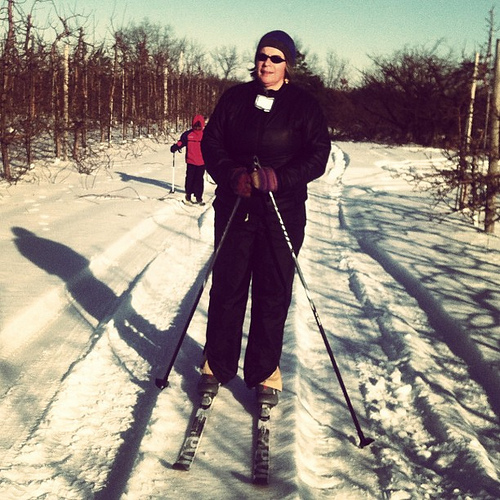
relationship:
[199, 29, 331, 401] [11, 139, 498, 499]
person on trail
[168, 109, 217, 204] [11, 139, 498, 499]
skier on trail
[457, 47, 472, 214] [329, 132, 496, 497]
tree of trail side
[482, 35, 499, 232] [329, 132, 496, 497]
tree of trail side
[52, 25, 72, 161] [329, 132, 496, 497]
tree of trail side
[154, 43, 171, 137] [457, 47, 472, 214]
tree of tree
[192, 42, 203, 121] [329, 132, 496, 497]
tree of trail side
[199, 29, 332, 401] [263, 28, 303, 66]
person wearing hat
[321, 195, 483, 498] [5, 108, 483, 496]
tracks in snow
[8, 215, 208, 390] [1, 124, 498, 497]
shadow on ground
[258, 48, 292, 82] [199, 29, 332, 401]
face of person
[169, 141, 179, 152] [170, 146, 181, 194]
hand holding pole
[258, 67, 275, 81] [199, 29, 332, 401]
mouth of person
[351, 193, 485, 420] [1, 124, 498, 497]
shadows of trees on ground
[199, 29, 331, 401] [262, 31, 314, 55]
person has on hat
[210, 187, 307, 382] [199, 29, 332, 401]
pants on person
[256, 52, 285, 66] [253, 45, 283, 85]
glasses on face